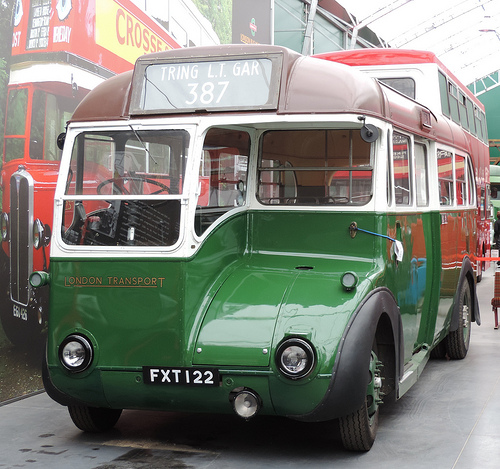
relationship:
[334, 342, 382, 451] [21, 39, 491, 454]
tire on bus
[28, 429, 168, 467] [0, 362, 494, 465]
spots on ground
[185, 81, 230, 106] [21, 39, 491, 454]
387 on bus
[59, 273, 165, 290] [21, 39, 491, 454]
london transport on bus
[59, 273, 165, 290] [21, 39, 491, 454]
london transport are on front of bus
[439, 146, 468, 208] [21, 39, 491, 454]
window on bus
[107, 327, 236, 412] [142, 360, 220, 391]
license plate with letters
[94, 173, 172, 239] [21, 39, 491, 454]
steering wheel inside bus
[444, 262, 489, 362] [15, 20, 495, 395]
tire of bus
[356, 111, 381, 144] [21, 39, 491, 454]
mirror on bus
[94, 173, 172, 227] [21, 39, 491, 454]
steering wheel in bus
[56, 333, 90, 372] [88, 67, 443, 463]
head light on bus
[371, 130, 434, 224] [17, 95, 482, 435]
window on side of bus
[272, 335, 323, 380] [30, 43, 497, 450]
head light on a vehicle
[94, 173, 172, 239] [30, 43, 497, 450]
steering wheel on a vehicle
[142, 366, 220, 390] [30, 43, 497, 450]
license plate on vehicle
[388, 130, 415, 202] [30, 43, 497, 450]
window on vehicle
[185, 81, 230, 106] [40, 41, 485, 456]
387 on a bus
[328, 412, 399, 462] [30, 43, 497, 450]
tire on a vehicle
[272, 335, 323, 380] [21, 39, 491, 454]
head light on bus